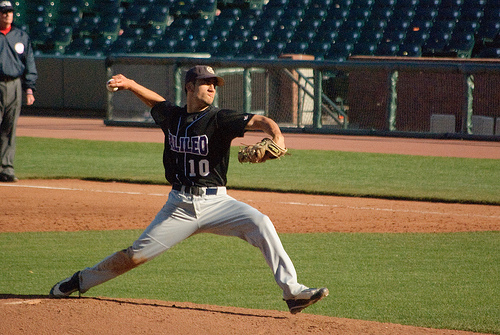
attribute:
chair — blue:
[335, 56, 345, 77]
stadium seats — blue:
[25, 1, 490, 54]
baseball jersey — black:
[148, 98, 253, 185]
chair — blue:
[317, 47, 342, 64]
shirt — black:
[150, 97, 255, 186]